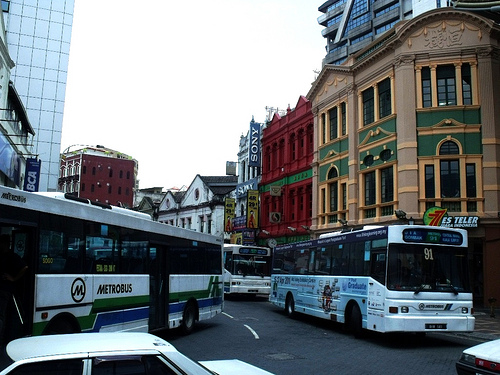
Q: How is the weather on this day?
A: It is cloudy.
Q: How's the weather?
A: It is cloudy.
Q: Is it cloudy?
A: Yes, it is cloudy.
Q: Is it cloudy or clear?
A: It is cloudy.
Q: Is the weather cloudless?
A: No, it is cloudy.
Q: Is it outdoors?
A: Yes, it is outdoors.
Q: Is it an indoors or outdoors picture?
A: It is outdoors.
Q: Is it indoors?
A: No, it is outdoors.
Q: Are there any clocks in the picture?
A: No, there are no clocks.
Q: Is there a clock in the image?
A: No, there are no clocks.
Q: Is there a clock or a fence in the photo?
A: No, there are no clocks or fences.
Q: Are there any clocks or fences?
A: No, there are no clocks or fences.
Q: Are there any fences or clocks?
A: No, there are no clocks or fences.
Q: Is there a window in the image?
A: Yes, there are windows.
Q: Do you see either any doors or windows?
A: Yes, there are windows.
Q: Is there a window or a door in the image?
A: Yes, there are windows.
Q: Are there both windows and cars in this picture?
A: Yes, there are both windows and a car.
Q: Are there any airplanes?
A: No, there are no airplanes.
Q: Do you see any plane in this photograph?
A: No, there are no airplanes.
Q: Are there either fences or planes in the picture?
A: No, there are no planes or fences.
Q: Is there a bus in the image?
A: Yes, there is a bus.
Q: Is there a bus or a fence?
A: Yes, there is a bus.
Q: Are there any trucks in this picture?
A: No, there are no trucks.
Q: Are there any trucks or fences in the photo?
A: No, there are no trucks or fences.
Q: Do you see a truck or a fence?
A: No, there are no trucks or fences.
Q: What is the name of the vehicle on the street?
A: The vehicle is a bus.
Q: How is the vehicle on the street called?
A: The vehicle is a bus.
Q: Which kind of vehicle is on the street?
A: The vehicle is a bus.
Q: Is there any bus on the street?
A: Yes, there is a bus on the street.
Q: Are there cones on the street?
A: No, there is a bus on the street.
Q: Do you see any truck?
A: No, there are no trucks.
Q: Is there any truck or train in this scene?
A: No, there are no trucks or trains.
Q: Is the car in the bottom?
A: Yes, the car is in the bottom of the image.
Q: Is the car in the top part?
A: No, the car is in the bottom of the image.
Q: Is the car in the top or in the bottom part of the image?
A: The car is in the bottom of the image.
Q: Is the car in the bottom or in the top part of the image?
A: The car is in the bottom of the image.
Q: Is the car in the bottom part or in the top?
A: The car is in the bottom of the image.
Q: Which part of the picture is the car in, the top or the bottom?
A: The car is in the bottom of the image.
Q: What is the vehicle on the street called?
A: The vehicle is a car.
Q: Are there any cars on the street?
A: Yes, there is a car on the street.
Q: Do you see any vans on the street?
A: No, there is a car on the street.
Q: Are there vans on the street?
A: No, there is a car on the street.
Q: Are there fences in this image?
A: No, there are no fences.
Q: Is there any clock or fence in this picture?
A: No, there are no fences or clocks.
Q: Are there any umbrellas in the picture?
A: No, there are no umbrellas.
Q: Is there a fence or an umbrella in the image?
A: No, there are no umbrellas or fences.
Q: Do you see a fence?
A: No, there are no fences.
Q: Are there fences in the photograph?
A: No, there are no fences.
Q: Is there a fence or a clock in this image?
A: No, there are no fences or clocks.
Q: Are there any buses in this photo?
A: Yes, there is a bus.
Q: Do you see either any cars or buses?
A: Yes, there is a bus.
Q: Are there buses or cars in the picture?
A: Yes, there is a bus.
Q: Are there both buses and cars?
A: Yes, there are both a bus and a car.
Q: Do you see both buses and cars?
A: Yes, there are both a bus and a car.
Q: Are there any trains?
A: No, there are no trains.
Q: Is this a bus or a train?
A: This is a bus.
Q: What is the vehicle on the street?
A: The vehicle is a bus.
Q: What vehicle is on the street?
A: The vehicle is a bus.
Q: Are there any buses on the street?
A: Yes, there is a bus on the street.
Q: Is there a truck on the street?
A: No, there is a bus on the street.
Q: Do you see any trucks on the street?
A: No, there is a bus on the street.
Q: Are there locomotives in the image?
A: No, there are no locomotives.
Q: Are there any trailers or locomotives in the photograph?
A: No, there are no locomotives or trailers.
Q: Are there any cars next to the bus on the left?
A: Yes, there is a car next to the bus.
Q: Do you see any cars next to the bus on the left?
A: Yes, there is a car next to the bus.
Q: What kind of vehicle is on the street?
A: The vehicle is a car.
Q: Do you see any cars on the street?
A: Yes, there is a car on the street.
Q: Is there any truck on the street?
A: No, there is a car on the street.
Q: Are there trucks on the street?
A: No, there is a car on the street.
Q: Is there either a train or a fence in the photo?
A: No, there are no trains or fences.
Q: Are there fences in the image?
A: No, there are no fences.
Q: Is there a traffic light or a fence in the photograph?
A: No, there are no fences or traffic lights.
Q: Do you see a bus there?
A: Yes, there is a bus.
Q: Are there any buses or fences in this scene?
A: Yes, there is a bus.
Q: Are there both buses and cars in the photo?
A: Yes, there are both a bus and a car.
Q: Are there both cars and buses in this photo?
A: Yes, there are both a bus and a car.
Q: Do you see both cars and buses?
A: Yes, there are both a bus and a car.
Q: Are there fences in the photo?
A: No, there are no fences.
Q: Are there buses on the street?
A: Yes, there is a bus on the street.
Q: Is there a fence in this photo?
A: No, there are no fences.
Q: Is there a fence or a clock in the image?
A: No, there are no fences or clocks.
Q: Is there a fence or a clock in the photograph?
A: No, there are no fences or clocks.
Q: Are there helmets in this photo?
A: No, there are no helmets.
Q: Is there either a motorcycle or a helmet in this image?
A: No, there are no helmets or motorcycles.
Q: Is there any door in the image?
A: Yes, there is a door.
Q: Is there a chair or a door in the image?
A: Yes, there is a door.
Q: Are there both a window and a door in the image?
A: Yes, there are both a door and a window.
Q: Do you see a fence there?
A: No, there are no fences.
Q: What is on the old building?
A: The sign is on the building.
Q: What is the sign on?
A: The sign is on the building.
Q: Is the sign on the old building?
A: Yes, the sign is on the building.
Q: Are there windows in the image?
A: Yes, there is a window.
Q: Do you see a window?
A: Yes, there is a window.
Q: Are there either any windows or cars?
A: Yes, there is a window.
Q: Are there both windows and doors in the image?
A: Yes, there are both a window and a door.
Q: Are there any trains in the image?
A: No, there are no trains.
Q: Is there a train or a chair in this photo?
A: No, there are no trains or chairs.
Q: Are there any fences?
A: No, there are no fences.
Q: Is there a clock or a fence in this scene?
A: No, there are no fences or clocks.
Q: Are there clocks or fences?
A: No, there are no fences or clocks.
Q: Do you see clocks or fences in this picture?
A: No, there are no fences or clocks.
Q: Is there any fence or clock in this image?
A: No, there are no fences or clocks.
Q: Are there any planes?
A: No, there are no planes.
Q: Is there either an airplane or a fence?
A: No, there are no airplanes or fences.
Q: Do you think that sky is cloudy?
A: Yes, the sky is cloudy.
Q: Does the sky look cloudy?
A: Yes, the sky is cloudy.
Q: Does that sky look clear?
A: No, the sky is cloudy.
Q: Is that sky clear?
A: No, the sky is cloudy.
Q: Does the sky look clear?
A: No, the sky is cloudy.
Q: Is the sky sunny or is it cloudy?
A: The sky is cloudy.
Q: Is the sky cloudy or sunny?
A: The sky is cloudy.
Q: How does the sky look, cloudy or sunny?
A: The sky is cloudy.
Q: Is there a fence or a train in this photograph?
A: No, there are no fences or trains.